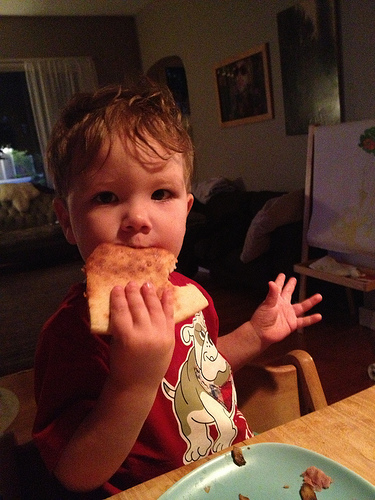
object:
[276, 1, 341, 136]
painting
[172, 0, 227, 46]
wall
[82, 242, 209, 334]
toasted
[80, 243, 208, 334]
bread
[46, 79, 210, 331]
eating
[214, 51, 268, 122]
picture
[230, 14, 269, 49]
wall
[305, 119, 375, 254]
painting easel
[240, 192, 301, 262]
pillow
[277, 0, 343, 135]
bad picture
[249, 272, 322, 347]
hand open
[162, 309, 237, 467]
bulldog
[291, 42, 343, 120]
bad sentance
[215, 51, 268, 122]
art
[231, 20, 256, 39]
wall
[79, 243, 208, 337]
pizza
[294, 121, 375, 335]
easel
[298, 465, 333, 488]
meat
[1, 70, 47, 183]
window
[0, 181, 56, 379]
couch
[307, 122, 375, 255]
table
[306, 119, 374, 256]
art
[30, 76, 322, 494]
little boy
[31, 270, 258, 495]
red shirt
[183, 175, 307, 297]
couch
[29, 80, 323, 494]
boy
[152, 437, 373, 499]
plate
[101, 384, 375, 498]
dining table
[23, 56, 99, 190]
curtains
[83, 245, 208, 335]
food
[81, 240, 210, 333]
slice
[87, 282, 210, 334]
down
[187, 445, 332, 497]
food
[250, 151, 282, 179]
wall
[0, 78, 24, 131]
night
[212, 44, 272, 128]
framed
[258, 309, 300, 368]
open